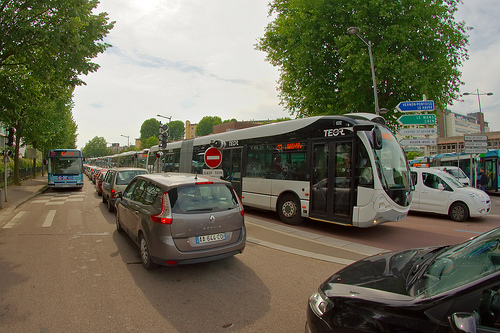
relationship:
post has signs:
[422, 95, 432, 159] [391, 100, 441, 151]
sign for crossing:
[203, 147, 225, 170] [22, 200, 189, 237]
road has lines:
[16, 189, 339, 297] [9, 209, 68, 239]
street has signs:
[224, 204, 498, 236] [391, 100, 441, 151]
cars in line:
[80, 162, 248, 265] [84, 158, 244, 261]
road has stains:
[16, 189, 339, 297] [70, 229, 109, 263]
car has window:
[118, 173, 248, 268] [174, 185, 236, 212]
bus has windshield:
[149, 115, 411, 229] [364, 125, 415, 189]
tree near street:
[267, 4, 472, 116] [224, 204, 498, 236]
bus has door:
[149, 115, 411, 229] [308, 136, 352, 221]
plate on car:
[193, 231, 229, 246] [118, 173, 248, 268]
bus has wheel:
[149, 115, 411, 229] [273, 190, 307, 229]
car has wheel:
[403, 167, 491, 224] [447, 202, 470, 221]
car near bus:
[403, 167, 491, 224] [149, 115, 411, 229]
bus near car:
[149, 115, 411, 229] [118, 173, 248, 268]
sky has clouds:
[87, 9, 281, 118] [158, 38, 231, 82]